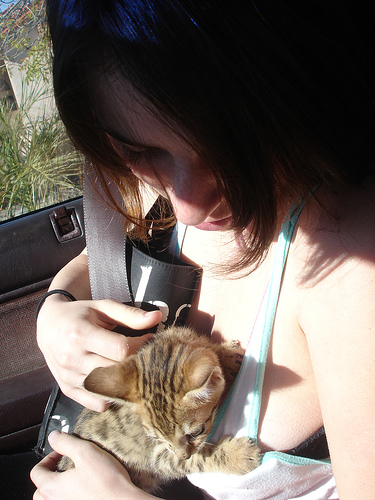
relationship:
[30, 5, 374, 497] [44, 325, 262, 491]
girl holding kitten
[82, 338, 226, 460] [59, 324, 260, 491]
head on cat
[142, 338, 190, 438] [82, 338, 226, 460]
stripe on head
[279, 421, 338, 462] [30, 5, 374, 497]
bra on girl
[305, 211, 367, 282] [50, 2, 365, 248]
shadow of hair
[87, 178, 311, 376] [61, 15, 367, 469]
shirt on woman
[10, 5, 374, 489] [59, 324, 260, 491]
girl holding cat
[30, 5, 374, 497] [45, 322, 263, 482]
girl holding kitten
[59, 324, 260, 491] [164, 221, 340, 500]
cat holding onto shirt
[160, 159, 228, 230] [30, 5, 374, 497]
nose on girl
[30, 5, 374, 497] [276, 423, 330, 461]
girl wearing bra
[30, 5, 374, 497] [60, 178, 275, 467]
girl wearing seatbelt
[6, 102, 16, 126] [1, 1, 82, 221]
leaves by car window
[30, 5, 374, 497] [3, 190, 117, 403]
girl in car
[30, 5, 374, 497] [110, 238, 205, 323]
girl holds an object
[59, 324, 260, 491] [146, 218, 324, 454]
cat on a chest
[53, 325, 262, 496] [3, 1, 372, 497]
cat in car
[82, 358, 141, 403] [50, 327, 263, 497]
ear of a kitten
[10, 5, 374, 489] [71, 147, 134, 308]
girl wearing seatbelt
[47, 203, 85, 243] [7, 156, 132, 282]
door lock on door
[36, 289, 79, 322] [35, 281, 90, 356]
band on woman's writs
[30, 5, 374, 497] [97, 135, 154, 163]
girl has eye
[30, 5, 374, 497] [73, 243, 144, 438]
girl has hand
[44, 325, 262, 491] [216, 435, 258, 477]
kitten has front paw